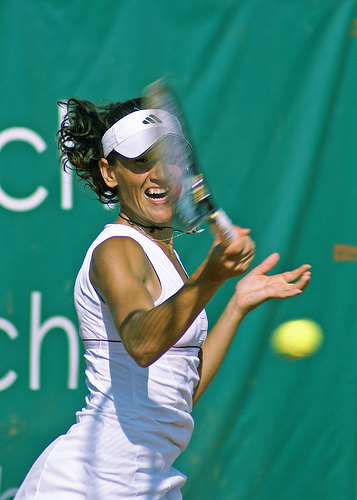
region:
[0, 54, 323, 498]
Tennis player kicking a ball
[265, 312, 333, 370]
Tennis ball flying in the air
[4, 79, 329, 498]
Tennis player wears a white dress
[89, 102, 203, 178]
White cap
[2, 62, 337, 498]
Woman has racket in left arm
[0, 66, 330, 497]
Woman has short hair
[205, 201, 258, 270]
Handle of racket is white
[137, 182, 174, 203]
Open mouth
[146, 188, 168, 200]
Teeth are white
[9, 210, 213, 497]
Dress is sleeveless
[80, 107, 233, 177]
Woman wearing white visor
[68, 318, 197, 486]
Woman wearing white tennis dress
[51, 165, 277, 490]
Woman playing tennis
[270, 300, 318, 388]
Tennis ball is green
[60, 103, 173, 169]
Woman has brown hair pulled back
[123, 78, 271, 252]
Woman is holding a tennis racquet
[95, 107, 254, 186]
White visor is Adidas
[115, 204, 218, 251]
Black necklace around woman's neck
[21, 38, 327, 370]
Blue wall behind player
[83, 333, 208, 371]
Black stripe around woman's dress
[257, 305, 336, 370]
tennis ball is in the air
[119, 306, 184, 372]
woman's elbow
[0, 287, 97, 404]
white letters on the green board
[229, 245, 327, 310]
left hand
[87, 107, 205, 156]
white visor with a black design on the front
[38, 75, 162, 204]
brown hair in a pony tail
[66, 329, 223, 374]
dark colored trim on white outfit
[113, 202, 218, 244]
necklace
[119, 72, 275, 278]
player is swinging the racket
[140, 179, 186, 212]
lady is opening her mouth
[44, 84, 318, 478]
tennis player showing emotion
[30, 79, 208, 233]
dark curls flying behind visor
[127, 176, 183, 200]
mouth open with teeth showing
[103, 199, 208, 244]
necklace pendent flying upwards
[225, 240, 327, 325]
hand held open with palm up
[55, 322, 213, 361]
thin black band across tennis dress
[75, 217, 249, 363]
bent elbow with shadows of tennis strings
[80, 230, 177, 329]
muscular arm in sleeveless dress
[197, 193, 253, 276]
hand gripped around tennis racket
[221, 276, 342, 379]
yellow ball moving through air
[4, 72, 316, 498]
Tennis player smiling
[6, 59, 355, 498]
Player kicking a ball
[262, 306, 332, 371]
Ball is in motion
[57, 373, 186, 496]
Shadow of racket on cloths of player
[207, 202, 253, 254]
Handle of tennis racket is white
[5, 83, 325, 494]
Tennis player wears white dress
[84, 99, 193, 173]
Cap of tennis player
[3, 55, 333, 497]
Tennis player has a racket on left hand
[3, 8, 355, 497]
Background is green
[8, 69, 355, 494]
Tennis player has black hair